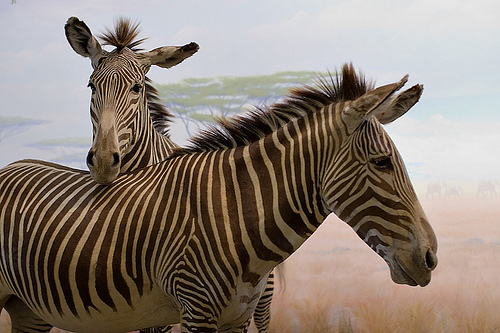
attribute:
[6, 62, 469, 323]
zebra — black, white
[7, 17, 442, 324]
zebras — here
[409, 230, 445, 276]
nose — grey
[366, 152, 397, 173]
eye — black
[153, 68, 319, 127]
tree — hazy, pale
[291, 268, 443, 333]
grass — hazy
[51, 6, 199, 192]
zebra — black, white, looking forward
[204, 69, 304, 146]
mane — black, white, spikey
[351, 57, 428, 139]
ears — pointing, pointy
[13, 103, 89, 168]
trees — distant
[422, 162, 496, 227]
animals — distant, african, tropical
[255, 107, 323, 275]
neck — thin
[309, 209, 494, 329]
field — brown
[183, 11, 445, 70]
sky — clear